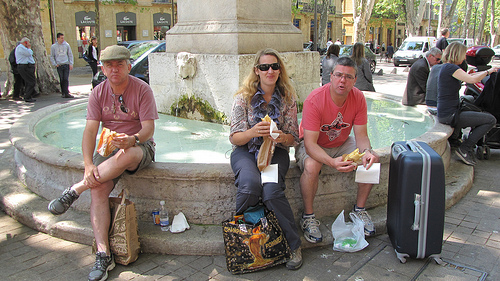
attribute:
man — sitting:
[47, 44, 159, 280]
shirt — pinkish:
[79, 73, 159, 145]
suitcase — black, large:
[386, 136, 448, 269]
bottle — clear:
[157, 197, 172, 234]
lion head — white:
[177, 49, 198, 83]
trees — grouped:
[294, 2, 499, 53]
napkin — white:
[354, 160, 383, 188]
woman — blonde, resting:
[435, 39, 499, 165]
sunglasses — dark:
[256, 62, 281, 72]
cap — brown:
[98, 44, 133, 63]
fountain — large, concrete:
[1, 1, 477, 258]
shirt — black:
[434, 60, 465, 122]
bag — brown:
[91, 187, 144, 267]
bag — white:
[330, 207, 371, 256]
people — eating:
[47, 42, 381, 279]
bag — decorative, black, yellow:
[222, 203, 294, 277]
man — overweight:
[14, 37, 39, 104]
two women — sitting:
[321, 40, 377, 93]